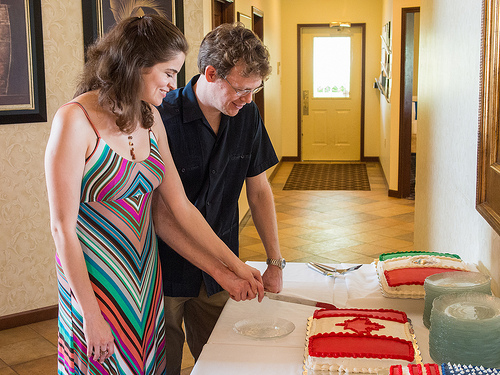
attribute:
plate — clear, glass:
[432, 263, 478, 298]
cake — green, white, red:
[370, 242, 494, 299]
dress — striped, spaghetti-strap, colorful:
[52, 100, 167, 372]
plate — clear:
[232, 316, 295, 340]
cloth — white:
[188, 258, 498, 373]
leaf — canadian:
[330, 314, 398, 339]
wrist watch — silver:
[265, 258, 286, 269]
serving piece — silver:
[258, 284, 336, 321]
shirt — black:
[156, 72, 279, 297]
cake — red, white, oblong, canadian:
[302, 303, 424, 375]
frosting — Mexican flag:
[378, 251, 475, 296]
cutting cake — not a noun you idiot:
[225, 266, 382, 352]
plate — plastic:
[428, 299, 491, 325]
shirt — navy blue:
[167, 79, 275, 270]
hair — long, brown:
[74, 16, 187, 136]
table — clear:
[188, 249, 495, 373]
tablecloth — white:
[187, 260, 491, 374]